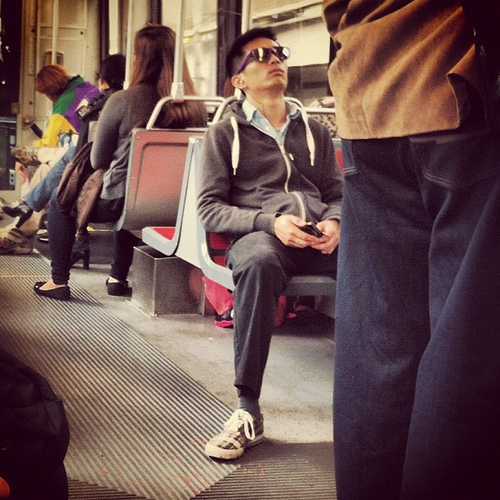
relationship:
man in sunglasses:
[235, 38, 347, 341] [231, 38, 302, 70]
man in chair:
[235, 38, 347, 341] [189, 135, 342, 302]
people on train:
[11, 12, 339, 341] [12, 6, 486, 412]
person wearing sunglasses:
[235, 38, 347, 341] [231, 38, 302, 70]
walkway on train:
[8, 230, 169, 462] [12, 6, 486, 412]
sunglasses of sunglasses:
[239, 45, 285, 76] [231, 38, 302, 70]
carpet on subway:
[8, 230, 169, 462] [12, 6, 486, 412]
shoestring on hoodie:
[221, 115, 268, 177] [204, 107, 359, 271]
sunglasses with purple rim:
[231, 38, 302, 70] [237, 49, 272, 78]